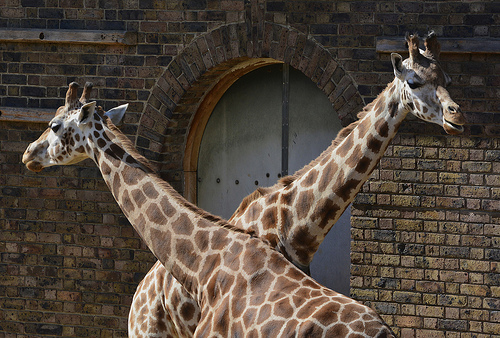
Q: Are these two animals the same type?
A: Yes, all the animals are giraffes.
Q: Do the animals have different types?
A: No, all the animals are giraffes.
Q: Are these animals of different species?
A: No, all the animals are giraffes.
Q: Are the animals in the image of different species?
A: No, all the animals are giraffes.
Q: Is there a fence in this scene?
A: No, there are no fences.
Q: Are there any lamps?
A: No, there are no lamps.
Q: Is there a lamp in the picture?
A: No, there are no lamps.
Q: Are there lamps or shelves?
A: No, there are no lamps or shelves.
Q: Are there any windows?
A: Yes, there is a window.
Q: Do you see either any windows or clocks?
A: Yes, there is a window.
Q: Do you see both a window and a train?
A: No, there is a window but no trains.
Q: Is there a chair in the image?
A: No, there are no chairs.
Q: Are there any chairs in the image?
A: No, there are no chairs.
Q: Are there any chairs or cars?
A: No, there are no chairs or cars.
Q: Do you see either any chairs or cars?
A: No, there are no chairs or cars.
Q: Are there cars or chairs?
A: No, there are no chairs or cars.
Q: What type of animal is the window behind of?
A: The window is behind the giraffe.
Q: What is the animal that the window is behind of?
A: The animal is a giraffe.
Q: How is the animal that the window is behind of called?
A: The animal is a giraffe.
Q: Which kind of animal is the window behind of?
A: The window is behind the giraffe.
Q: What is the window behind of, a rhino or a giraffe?
A: The window is behind a giraffe.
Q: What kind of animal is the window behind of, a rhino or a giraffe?
A: The window is behind a giraffe.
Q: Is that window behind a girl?
A: No, the window is behind the giraffe.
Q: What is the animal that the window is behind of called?
A: The animal is a giraffe.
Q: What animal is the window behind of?
A: The window is behind the giraffe.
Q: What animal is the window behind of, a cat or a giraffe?
A: The window is behind a giraffe.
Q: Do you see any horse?
A: No, there are no horses.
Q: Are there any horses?
A: No, there are no horses.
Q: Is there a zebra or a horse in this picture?
A: No, there are no horses or zebras.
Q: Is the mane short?
A: Yes, the mane is short.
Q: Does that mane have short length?
A: Yes, the mane is short.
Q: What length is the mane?
A: The mane is short.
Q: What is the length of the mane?
A: The mane is short.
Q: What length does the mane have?
A: The mane has short length.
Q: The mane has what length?
A: The mane is short.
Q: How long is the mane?
A: The mane is short.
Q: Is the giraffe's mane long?
A: No, the mane is short.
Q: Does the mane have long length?
A: No, the mane is short.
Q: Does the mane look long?
A: No, the mane is short.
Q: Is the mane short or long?
A: The mane is short.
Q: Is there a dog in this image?
A: No, there are no dogs.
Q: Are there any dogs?
A: No, there are no dogs.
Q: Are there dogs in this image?
A: No, there are no dogs.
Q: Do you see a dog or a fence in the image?
A: No, there are no dogs or fences.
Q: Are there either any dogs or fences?
A: No, there are no dogs or fences.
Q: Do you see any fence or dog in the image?
A: No, there are no dogs or fences.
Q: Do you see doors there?
A: Yes, there is a door.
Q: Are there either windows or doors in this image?
A: Yes, there is a door.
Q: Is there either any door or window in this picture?
A: Yes, there is a door.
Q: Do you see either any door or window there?
A: Yes, there is a door.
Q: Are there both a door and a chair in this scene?
A: No, there is a door but no chairs.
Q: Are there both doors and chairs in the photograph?
A: No, there is a door but no chairs.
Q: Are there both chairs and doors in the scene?
A: No, there is a door but no chairs.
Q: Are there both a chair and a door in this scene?
A: No, there is a door but no chairs.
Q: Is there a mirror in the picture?
A: No, there are no mirrors.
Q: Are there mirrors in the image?
A: No, there are no mirrors.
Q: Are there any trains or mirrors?
A: No, there are no mirrors or trains.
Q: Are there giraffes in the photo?
A: Yes, there is a giraffe.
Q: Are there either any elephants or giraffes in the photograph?
A: Yes, there is a giraffe.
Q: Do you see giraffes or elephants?
A: Yes, there is a giraffe.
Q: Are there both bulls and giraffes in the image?
A: No, there is a giraffe but no bulls.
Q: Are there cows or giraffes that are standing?
A: Yes, the giraffe is standing.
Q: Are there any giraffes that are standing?
A: Yes, there is a giraffe that is standing.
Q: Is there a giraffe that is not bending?
A: Yes, there is a giraffe that is standing.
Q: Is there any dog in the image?
A: No, there are no dogs.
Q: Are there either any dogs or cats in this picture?
A: No, there are no dogs or cats.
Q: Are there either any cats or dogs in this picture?
A: No, there are no dogs or cats.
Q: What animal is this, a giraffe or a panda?
A: This is a giraffe.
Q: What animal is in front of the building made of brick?
A: The giraffe is in front of the building.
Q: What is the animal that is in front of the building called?
A: The animal is a giraffe.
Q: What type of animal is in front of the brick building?
A: The animal is a giraffe.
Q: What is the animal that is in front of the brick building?
A: The animal is a giraffe.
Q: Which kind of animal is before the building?
A: The animal is a giraffe.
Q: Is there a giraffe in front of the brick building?
A: Yes, there is a giraffe in front of the building.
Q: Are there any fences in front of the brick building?
A: No, there is a giraffe in front of the building.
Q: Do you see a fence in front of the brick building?
A: No, there is a giraffe in front of the building.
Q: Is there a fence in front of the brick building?
A: No, there is a giraffe in front of the building.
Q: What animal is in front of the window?
A: The giraffe is in front of the window.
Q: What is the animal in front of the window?
A: The animal is a giraffe.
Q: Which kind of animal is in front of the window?
A: The animal is a giraffe.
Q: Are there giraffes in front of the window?
A: Yes, there is a giraffe in front of the window.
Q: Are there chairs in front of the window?
A: No, there is a giraffe in front of the window.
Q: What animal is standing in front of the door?
A: The giraffe is standing in front of the door.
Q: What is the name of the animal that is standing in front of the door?
A: The animal is a giraffe.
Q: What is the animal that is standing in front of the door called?
A: The animal is a giraffe.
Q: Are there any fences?
A: No, there are no fences.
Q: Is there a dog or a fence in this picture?
A: No, there are no fences or dogs.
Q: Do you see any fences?
A: No, there are no fences.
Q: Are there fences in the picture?
A: No, there are no fences.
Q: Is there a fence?
A: No, there are no fences.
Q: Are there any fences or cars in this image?
A: No, there are no fences or cars.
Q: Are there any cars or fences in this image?
A: No, there are no fences or cars.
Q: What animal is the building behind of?
A: The building is behind the giraffe.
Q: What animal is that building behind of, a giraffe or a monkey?
A: The building is behind a giraffe.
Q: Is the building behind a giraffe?
A: Yes, the building is behind a giraffe.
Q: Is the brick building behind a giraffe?
A: Yes, the building is behind a giraffe.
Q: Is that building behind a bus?
A: No, the building is behind a giraffe.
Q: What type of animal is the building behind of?
A: The building is behind the giraffe.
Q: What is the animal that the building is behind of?
A: The animal is a giraffe.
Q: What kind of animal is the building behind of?
A: The building is behind the giraffe.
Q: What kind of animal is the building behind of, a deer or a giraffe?
A: The building is behind a giraffe.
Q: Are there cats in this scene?
A: No, there are no cats.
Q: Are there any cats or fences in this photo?
A: No, there are no cats or fences.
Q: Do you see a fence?
A: No, there are no fences.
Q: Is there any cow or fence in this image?
A: No, there are no fences or cows.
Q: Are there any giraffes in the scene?
A: Yes, there is a giraffe.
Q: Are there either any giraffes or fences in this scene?
A: Yes, there is a giraffe.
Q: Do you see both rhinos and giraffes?
A: No, there is a giraffe but no rhinos.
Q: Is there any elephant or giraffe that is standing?
A: Yes, the giraffe is standing.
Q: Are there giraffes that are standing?
A: Yes, there is a giraffe that is standing.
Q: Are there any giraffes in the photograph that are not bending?
A: Yes, there is a giraffe that is standing.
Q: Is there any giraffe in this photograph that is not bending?
A: Yes, there is a giraffe that is standing.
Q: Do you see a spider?
A: No, there are no spiders.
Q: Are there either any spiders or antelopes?
A: No, there are no spiders or antelopes.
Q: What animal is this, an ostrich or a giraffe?
A: This is a giraffe.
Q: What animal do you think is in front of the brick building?
A: The giraffe is in front of the building.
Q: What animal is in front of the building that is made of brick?
A: The giraffe is in front of the building.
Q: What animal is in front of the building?
A: The giraffe is in front of the building.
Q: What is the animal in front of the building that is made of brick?
A: The animal is a giraffe.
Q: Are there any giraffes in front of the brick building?
A: Yes, there is a giraffe in front of the building.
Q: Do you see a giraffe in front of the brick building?
A: Yes, there is a giraffe in front of the building.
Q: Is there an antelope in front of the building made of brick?
A: No, there is a giraffe in front of the building.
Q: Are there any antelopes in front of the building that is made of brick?
A: No, there is a giraffe in front of the building.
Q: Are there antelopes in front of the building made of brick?
A: No, there is a giraffe in front of the building.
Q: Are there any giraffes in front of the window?
A: Yes, there is a giraffe in front of the window.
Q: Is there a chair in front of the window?
A: No, there is a giraffe in front of the window.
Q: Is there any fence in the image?
A: No, there are no fences.